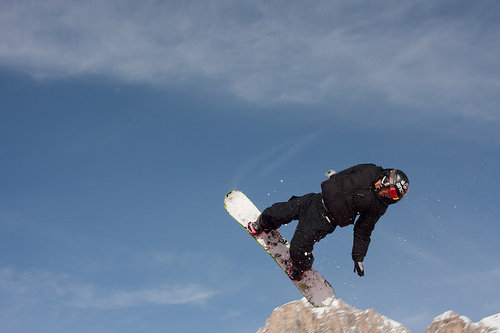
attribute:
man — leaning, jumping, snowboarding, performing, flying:
[248, 160, 411, 278]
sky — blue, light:
[2, 2, 498, 331]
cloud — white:
[2, 3, 498, 129]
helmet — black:
[378, 168, 411, 201]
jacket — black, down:
[318, 161, 386, 264]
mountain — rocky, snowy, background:
[253, 296, 420, 332]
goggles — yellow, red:
[387, 165, 401, 201]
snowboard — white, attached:
[223, 186, 337, 310]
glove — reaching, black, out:
[352, 259, 366, 276]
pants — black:
[256, 192, 340, 278]